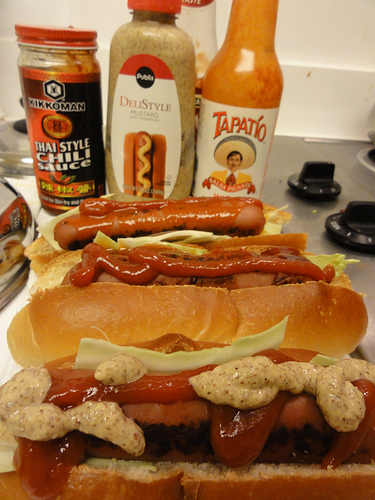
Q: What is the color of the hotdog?
A: Brown.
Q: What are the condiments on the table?
A: Mustard, chili sauce.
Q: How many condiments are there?
A: Three.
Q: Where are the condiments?
A: Behind the hotdogs.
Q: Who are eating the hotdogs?
A: No one.